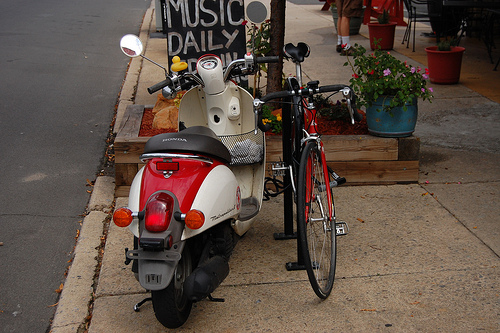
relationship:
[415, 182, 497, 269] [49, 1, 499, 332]
cracks in pavement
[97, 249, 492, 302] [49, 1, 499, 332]
cracks in pavement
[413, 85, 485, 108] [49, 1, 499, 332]
cracks in pavement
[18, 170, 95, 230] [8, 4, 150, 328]
pavement on road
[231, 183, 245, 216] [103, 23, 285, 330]
design on scooter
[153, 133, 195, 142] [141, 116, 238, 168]
writing on scooter seat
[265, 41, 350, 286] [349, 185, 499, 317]
bicycle parked on sidewalk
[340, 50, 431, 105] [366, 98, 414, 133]
plant in pot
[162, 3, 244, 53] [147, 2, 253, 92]
writing on sign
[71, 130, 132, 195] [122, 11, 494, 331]
trash beside sidewalk